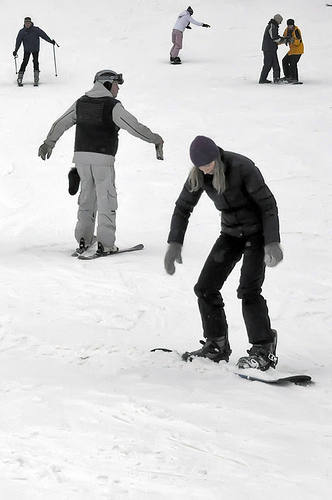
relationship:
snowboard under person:
[149, 347, 313, 386] [166, 135, 283, 368]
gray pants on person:
[78, 150, 114, 241] [166, 135, 283, 368]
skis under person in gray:
[78, 248, 147, 258] [78, 150, 114, 241]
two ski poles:
[12, 15, 59, 88] [51, 44, 59, 79]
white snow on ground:
[56, 427, 163, 489] [2, 271, 83, 361]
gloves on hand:
[39, 141, 56, 162] [152, 145, 168, 162]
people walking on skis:
[36, 66, 166, 254] [78, 248, 147, 258]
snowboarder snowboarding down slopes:
[167, 4, 211, 66] [105, 3, 161, 62]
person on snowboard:
[166, 135, 283, 368] [222, 359, 308, 385]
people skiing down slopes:
[36, 66, 166, 254] [105, 3, 161, 62]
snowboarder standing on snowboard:
[167, 4, 211, 66] [222, 359, 308, 385]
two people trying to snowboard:
[257, 15, 302, 87] [222, 359, 308, 385]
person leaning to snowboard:
[166, 135, 283, 368] [222, 359, 308, 385]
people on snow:
[15, 5, 313, 389] [26, 397, 129, 470]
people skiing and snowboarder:
[15, 5, 313, 389] [167, 4, 211, 66]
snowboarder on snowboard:
[167, 4, 211, 66] [222, 359, 308, 385]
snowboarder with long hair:
[167, 4, 211, 66] [214, 163, 222, 192]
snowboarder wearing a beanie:
[167, 4, 211, 66] [189, 137, 216, 160]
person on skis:
[166, 135, 283, 368] [78, 248, 147, 258]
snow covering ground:
[26, 397, 129, 470] [2, 271, 83, 361]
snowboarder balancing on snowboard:
[167, 4, 211, 66] [222, 359, 308, 385]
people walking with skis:
[36, 66, 166, 254] [78, 248, 147, 258]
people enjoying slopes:
[15, 5, 313, 389] [115, 3, 162, 61]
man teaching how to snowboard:
[261, 13, 286, 79] [222, 359, 308, 385]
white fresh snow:
[56, 427, 163, 489] [26, 397, 129, 470]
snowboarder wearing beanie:
[167, 4, 211, 66] [189, 137, 216, 160]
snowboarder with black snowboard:
[167, 4, 211, 66] [149, 347, 313, 386]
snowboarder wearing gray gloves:
[167, 4, 211, 66] [39, 141, 56, 162]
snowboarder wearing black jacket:
[167, 4, 211, 66] [183, 176, 269, 242]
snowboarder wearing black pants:
[167, 4, 211, 66] [210, 238, 261, 344]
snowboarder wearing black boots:
[167, 4, 211, 66] [202, 331, 277, 369]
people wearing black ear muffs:
[36, 66, 166, 254] [105, 80, 110, 90]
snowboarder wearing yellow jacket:
[167, 4, 211, 66] [282, 28, 303, 54]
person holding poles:
[12, 15, 59, 88] [51, 44, 59, 79]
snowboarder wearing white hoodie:
[167, 4, 211, 66] [175, 16, 197, 32]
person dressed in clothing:
[166, 135, 283, 368] [163, 146, 282, 343]